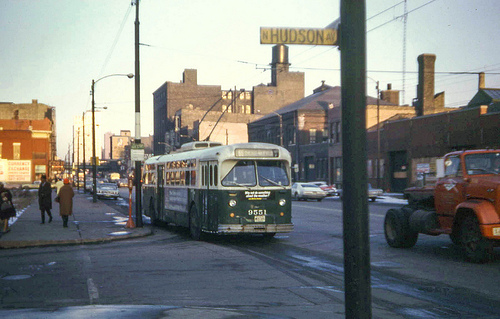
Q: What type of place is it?
A: It is a road.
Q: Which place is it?
A: It is a road.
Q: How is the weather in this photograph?
A: It is cloudy.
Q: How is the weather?
A: It is cloudy.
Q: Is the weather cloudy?
A: Yes, it is cloudy.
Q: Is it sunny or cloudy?
A: It is cloudy.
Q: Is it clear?
A: No, it is cloudy.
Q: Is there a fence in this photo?
A: No, there are no fences.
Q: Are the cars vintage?
A: Yes, the cars are vintage.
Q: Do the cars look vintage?
A: Yes, the cars are vintage.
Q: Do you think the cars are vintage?
A: Yes, the cars are vintage.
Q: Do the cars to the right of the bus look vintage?
A: Yes, the cars are vintage.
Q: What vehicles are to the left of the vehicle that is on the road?
A: The vehicles are cars.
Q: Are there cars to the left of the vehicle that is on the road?
A: Yes, there are cars to the left of the vehicle.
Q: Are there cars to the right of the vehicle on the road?
A: No, the cars are to the left of the vehicle.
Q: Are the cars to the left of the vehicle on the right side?
A: Yes, the cars are to the left of the vehicle.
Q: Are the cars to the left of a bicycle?
A: No, the cars are to the left of the vehicle.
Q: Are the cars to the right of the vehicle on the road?
A: No, the cars are to the left of the vehicle.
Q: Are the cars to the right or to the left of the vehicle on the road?
A: The cars are to the left of the vehicle.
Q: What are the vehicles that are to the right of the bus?
A: The vehicles are cars.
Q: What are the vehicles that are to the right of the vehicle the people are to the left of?
A: The vehicles are cars.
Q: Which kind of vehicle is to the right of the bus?
A: The vehicles are cars.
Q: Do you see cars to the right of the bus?
A: Yes, there are cars to the right of the bus.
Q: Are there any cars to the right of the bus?
A: Yes, there are cars to the right of the bus.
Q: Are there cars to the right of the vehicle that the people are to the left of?
A: Yes, there are cars to the right of the bus.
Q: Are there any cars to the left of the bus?
A: No, the cars are to the right of the bus.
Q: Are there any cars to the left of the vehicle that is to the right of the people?
A: No, the cars are to the right of the bus.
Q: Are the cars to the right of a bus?
A: Yes, the cars are to the right of a bus.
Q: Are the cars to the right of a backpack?
A: No, the cars are to the right of a bus.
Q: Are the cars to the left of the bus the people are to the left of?
A: No, the cars are to the right of the bus.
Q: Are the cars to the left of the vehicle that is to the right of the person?
A: No, the cars are to the right of the bus.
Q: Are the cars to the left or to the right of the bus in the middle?
A: The cars are to the right of the bus.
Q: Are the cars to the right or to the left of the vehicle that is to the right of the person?
A: The cars are to the right of the bus.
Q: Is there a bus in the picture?
A: Yes, there is a bus.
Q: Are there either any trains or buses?
A: Yes, there is a bus.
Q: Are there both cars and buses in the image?
A: Yes, there are both a bus and a car.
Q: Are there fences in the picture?
A: No, there are no fences.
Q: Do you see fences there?
A: No, there are no fences.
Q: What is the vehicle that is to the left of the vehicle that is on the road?
A: The vehicle is a bus.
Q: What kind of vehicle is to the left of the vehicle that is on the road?
A: The vehicle is a bus.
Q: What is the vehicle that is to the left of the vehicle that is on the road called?
A: The vehicle is a bus.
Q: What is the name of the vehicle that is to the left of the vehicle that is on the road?
A: The vehicle is a bus.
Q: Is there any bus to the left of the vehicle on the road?
A: Yes, there is a bus to the left of the vehicle.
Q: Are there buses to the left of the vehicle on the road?
A: Yes, there is a bus to the left of the vehicle.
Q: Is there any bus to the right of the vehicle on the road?
A: No, the bus is to the left of the vehicle.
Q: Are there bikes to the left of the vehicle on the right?
A: No, there is a bus to the left of the vehicle.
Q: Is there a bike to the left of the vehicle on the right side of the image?
A: No, there is a bus to the left of the vehicle.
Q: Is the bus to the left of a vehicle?
A: Yes, the bus is to the left of a vehicle.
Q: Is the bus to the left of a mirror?
A: No, the bus is to the left of a vehicle.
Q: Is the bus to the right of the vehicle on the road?
A: No, the bus is to the left of the vehicle.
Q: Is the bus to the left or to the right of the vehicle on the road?
A: The bus is to the left of the vehicle.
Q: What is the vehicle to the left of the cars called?
A: The vehicle is a bus.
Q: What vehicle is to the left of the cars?
A: The vehicle is a bus.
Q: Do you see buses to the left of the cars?
A: Yes, there is a bus to the left of the cars.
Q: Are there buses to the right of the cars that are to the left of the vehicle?
A: No, the bus is to the left of the cars.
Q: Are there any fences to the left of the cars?
A: No, there is a bus to the left of the cars.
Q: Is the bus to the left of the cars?
A: Yes, the bus is to the left of the cars.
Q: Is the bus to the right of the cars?
A: No, the bus is to the left of the cars.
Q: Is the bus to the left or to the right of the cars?
A: The bus is to the left of the cars.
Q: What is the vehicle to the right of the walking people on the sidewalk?
A: The vehicle is a bus.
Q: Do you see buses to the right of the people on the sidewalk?
A: Yes, there is a bus to the right of the people.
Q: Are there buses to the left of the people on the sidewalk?
A: No, the bus is to the right of the people.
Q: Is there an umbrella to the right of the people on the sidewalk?
A: No, there is a bus to the right of the people.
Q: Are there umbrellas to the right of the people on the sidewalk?
A: No, there is a bus to the right of the people.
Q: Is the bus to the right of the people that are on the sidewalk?
A: Yes, the bus is to the right of the people.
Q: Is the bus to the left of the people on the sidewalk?
A: No, the bus is to the right of the people.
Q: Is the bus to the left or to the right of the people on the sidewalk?
A: The bus is to the right of the people.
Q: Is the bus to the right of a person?
A: Yes, the bus is to the right of a person.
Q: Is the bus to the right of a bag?
A: No, the bus is to the right of a person.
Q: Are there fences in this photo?
A: No, there are no fences.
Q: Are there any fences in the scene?
A: No, there are no fences.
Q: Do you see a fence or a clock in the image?
A: No, there are no fences or clocks.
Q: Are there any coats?
A: Yes, there is a coat.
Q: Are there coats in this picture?
A: Yes, there is a coat.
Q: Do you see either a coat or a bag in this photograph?
A: Yes, there is a coat.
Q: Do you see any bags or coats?
A: Yes, there is a coat.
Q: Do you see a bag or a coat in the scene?
A: Yes, there is a coat.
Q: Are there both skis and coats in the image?
A: No, there is a coat but no skis.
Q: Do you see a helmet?
A: No, there are no helmets.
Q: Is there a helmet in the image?
A: No, there are no helmets.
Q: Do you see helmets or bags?
A: No, there are no helmets or bags.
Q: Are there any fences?
A: No, there are no fences.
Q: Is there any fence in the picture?
A: No, there are no fences.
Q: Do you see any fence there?
A: No, there are no fences.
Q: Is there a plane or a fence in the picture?
A: No, there are no fences or airplanes.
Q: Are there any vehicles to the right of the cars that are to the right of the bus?
A: Yes, there is a vehicle to the right of the cars.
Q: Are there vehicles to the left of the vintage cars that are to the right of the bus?
A: No, the vehicle is to the right of the cars.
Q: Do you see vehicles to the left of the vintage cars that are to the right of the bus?
A: No, the vehicle is to the right of the cars.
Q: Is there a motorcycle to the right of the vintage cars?
A: No, there is a vehicle to the right of the cars.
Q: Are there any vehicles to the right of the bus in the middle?
A: Yes, there is a vehicle to the right of the bus.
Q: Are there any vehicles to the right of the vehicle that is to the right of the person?
A: Yes, there is a vehicle to the right of the bus.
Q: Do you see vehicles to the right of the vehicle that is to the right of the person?
A: Yes, there is a vehicle to the right of the bus.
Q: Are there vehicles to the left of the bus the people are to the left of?
A: No, the vehicle is to the right of the bus.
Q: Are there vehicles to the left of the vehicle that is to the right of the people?
A: No, the vehicle is to the right of the bus.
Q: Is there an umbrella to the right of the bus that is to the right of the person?
A: No, there is a vehicle to the right of the bus.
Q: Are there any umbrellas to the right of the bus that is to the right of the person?
A: No, there is a vehicle to the right of the bus.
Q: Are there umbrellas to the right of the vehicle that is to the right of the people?
A: No, there is a vehicle to the right of the bus.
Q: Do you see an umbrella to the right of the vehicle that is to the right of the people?
A: No, there is a vehicle to the right of the bus.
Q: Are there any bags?
A: No, there are no bags.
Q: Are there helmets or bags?
A: No, there are no bags or helmets.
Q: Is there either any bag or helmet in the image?
A: No, there are no bags or helmets.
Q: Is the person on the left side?
A: Yes, the person is on the left of the image.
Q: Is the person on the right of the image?
A: No, the person is on the left of the image.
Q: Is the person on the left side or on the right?
A: The person is on the left of the image.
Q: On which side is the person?
A: The person is on the left of the image.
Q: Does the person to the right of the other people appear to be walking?
A: Yes, the person is walking.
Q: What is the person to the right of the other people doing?
A: The person is walking.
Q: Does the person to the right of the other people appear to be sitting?
A: No, the person is walking.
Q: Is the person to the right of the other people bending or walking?
A: The person is walking.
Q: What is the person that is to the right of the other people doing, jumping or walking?
A: The person is walking.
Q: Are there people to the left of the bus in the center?
A: Yes, there is a person to the left of the bus.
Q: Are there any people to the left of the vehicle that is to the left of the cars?
A: Yes, there is a person to the left of the bus.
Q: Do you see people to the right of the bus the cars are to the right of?
A: No, the person is to the left of the bus.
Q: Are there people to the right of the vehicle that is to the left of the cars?
A: No, the person is to the left of the bus.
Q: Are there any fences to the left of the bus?
A: No, there is a person to the left of the bus.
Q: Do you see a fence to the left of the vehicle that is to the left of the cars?
A: No, there is a person to the left of the bus.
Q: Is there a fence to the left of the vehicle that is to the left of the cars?
A: No, there is a person to the left of the bus.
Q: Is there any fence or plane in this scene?
A: No, there are no fences or airplanes.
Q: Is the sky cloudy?
A: Yes, the sky is cloudy.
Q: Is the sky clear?
A: No, the sky is cloudy.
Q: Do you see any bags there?
A: No, there are no bags.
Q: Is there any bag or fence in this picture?
A: No, there are no bags or fences.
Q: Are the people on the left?
A: Yes, the people are on the left of the image.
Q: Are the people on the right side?
A: No, the people are on the left of the image.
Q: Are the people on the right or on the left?
A: The people are on the left of the image.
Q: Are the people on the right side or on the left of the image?
A: The people are on the left of the image.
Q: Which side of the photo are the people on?
A: The people are on the left of the image.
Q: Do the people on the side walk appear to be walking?
A: Yes, the people are walking.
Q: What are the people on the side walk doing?
A: The people are walking.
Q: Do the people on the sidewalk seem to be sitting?
A: No, the people are walking.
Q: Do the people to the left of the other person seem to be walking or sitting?
A: The people are walking.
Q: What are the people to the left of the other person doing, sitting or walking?
A: The people are walking.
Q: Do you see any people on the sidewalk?
A: Yes, there are people on the sidewalk.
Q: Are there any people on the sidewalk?
A: Yes, there are people on the sidewalk.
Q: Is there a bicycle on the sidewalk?
A: No, there are people on the sidewalk.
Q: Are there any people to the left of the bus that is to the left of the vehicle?
A: Yes, there are people to the left of the bus.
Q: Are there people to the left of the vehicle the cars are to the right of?
A: Yes, there are people to the left of the bus.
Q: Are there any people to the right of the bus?
A: No, the people are to the left of the bus.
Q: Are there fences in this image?
A: No, there are no fences.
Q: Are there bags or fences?
A: No, there are no fences or bags.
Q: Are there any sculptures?
A: No, there are no sculptures.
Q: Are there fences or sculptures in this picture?
A: No, there are no sculptures or fences.